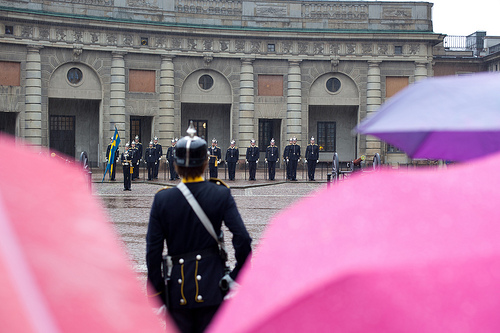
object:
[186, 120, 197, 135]
dome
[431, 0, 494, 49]
sky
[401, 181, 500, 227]
wall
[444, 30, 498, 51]
fence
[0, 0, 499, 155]
building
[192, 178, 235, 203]
shoulder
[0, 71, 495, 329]
ground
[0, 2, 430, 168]
front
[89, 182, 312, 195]
lines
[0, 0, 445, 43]
trimming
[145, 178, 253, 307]
jacket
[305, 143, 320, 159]
jacket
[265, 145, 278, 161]
jacket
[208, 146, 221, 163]
jacket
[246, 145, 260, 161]
jacket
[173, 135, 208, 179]
head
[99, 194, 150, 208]
water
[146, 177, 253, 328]
suit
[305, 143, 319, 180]
suit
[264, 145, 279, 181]
suit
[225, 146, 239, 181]
suit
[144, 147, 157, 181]
suit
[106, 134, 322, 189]
group men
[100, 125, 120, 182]
flag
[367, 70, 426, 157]
spine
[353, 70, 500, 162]
umbrella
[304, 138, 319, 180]
man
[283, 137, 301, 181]
man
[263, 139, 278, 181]
man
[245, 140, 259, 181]
man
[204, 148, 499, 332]
pink object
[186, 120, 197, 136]
hat/metal top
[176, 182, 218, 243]
sash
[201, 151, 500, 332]
umbrella top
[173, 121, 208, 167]
hat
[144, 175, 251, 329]
uniform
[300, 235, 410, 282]
object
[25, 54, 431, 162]
pillar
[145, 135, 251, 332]
man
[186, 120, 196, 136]
spike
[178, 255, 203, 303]
buttons